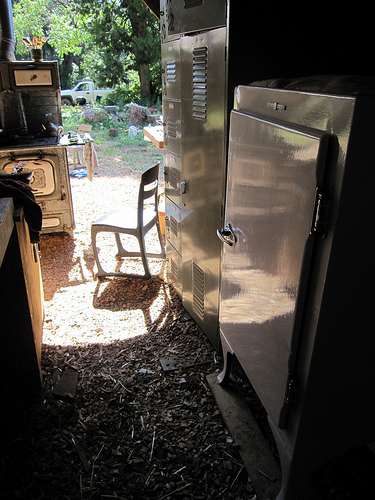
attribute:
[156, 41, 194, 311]
cabinets — metal, locker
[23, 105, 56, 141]
pot — old, coffee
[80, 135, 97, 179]
cloth — YELLOW, GREY, STRIPED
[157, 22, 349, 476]
containers — LARGE, SHINY, SILVER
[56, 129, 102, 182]
table — wooden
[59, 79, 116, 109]
truck — white